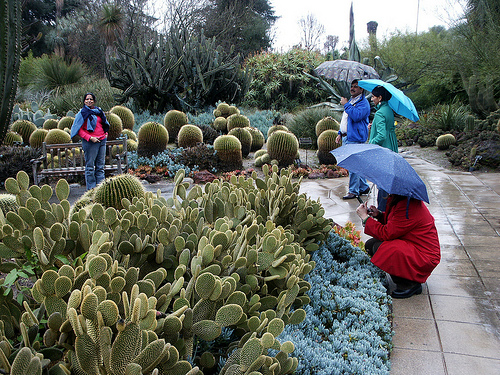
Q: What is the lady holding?
A: An umbrella.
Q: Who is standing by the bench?
A: A person.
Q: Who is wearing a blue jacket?
A: A man.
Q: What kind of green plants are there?
A: Cacti.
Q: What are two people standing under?
A: Umbrellas.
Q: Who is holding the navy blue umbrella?
A: A person.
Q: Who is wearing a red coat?
A: A person.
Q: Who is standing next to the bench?
A: A woman.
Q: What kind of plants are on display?
A: Cacti.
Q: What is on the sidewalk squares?
A: Wet cement.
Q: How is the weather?
A: Raining.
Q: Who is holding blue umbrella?
A: Person in red coat.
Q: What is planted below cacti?
A: Flowers.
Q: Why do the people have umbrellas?
A: It's raining.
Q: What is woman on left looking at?
A: The plants.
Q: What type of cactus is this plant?
A: Bush cactus.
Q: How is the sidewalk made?
A: Outdoor tiles.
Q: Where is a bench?
A: Behind woman on left.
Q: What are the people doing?
A: Holding umbrellas.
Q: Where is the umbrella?
A: Above the people.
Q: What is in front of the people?
A: Cacti.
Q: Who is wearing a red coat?
A: A lady.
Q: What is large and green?
A: A cactus.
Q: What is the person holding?
A: Umbrella.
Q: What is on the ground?
A: The bench.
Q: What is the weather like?
A: Rainy.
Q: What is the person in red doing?
A: Squatting.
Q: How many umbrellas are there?
A: Three.